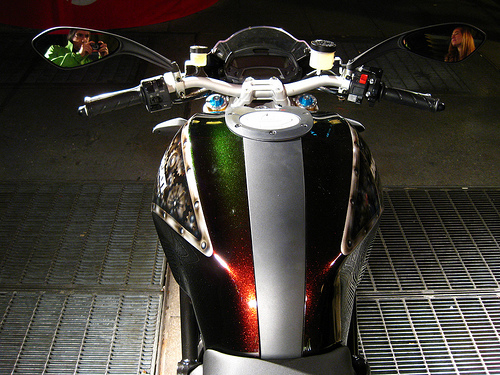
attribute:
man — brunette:
[47, 29, 104, 62]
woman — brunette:
[448, 28, 474, 66]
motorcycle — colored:
[25, 20, 492, 373]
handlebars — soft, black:
[74, 72, 457, 128]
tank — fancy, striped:
[145, 111, 409, 356]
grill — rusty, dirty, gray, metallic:
[2, 172, 500, 372]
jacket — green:
[47, 44, 92, 67]